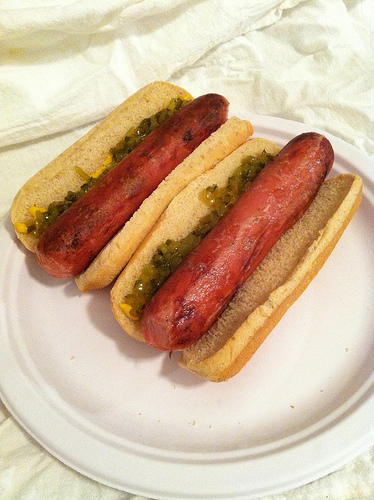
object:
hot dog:
[141, 131, 333, 353]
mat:
[19, 423, 121, 488]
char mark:
[182, 129, 194, 144]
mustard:
[93, 162, 107, 178]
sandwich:
[108, 134, 363, 382]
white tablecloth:
[0, 0, 373, 498]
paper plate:
[2, 111, 374, 497]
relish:
[206, 185, 232, 217]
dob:
[14, 220, 28, 235]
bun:
[9, 81, 255, 290]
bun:
[110, 135, 365, 383]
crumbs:
[188, 418, 191, 424]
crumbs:
[289, 402, 294, 411]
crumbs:
[344, 345, 350, 353]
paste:
[198, 188, 228, 202]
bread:
[108, 134, 361, 385]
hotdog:
[34, 91, 227, 280]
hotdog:
[136, 131, 334, 349]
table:
[0, 1, 373, 499]